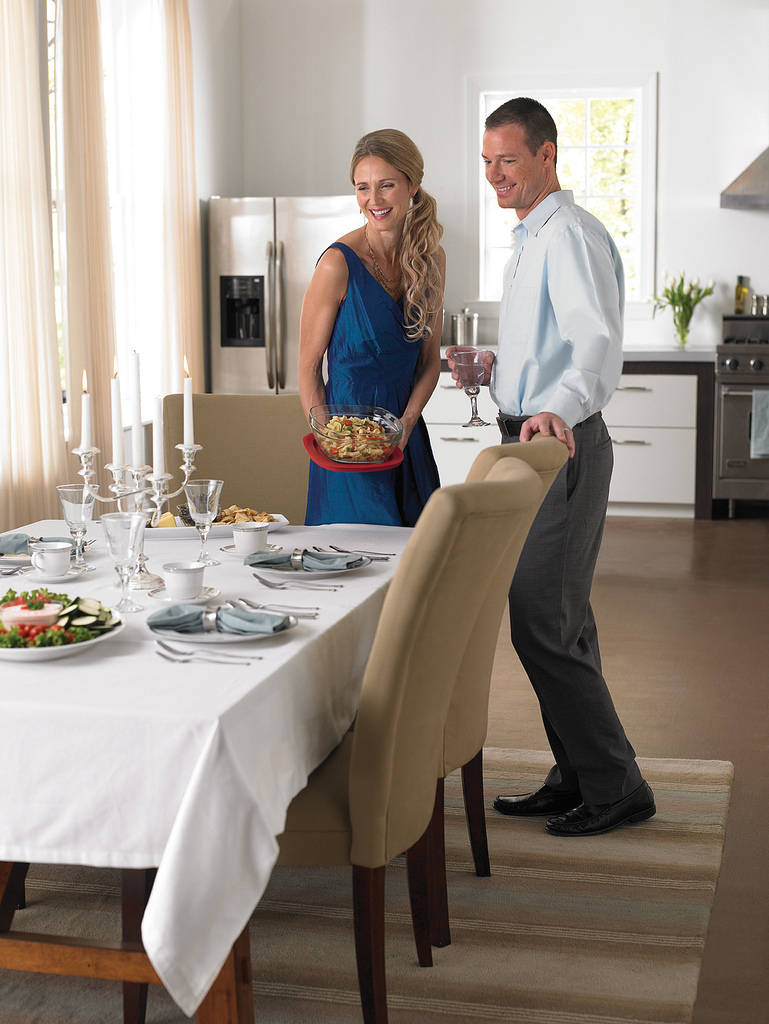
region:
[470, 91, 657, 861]
man wearing light blue shirt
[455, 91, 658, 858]
man wearing smoke gray pants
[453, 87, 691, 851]
man wearing black dress shoes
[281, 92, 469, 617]
woman wearing blue dress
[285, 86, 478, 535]
woman holding a dish of food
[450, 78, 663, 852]
man holding a wine glass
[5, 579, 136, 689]
plate with vegetables on it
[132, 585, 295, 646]
napkin with ring around it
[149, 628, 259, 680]
two forks on the table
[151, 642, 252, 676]
a utensil made for dining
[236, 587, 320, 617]
a utensil made for dining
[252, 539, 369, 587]
a plate made for dining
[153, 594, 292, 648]
a plate made for dining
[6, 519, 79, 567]
a plate made for dining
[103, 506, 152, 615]
a vessel made for drinking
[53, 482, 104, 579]
a vessel made for drinking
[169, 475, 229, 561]
a vessel made for drinking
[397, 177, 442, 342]
long ponytail hanging over the shoulder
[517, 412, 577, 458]
hand resting on top of the chair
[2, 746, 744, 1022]
area rug is laying on the floor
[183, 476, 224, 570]
clear, empty glass on the table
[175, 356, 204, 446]
candle is lit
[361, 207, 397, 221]
big smile on the face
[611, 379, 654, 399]
silver handle on the drawer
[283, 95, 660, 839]
a woman is standing next to a man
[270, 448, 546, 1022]
chair is pushed into the table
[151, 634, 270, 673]
silverware laying on the table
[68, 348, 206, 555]
a candelabra with white candles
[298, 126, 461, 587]
a woman with a blonde side ponytail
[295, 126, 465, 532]
woman wearing a blue dress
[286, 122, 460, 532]
woman holding dish of food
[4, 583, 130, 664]
a platter with vegetables and dip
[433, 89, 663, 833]
man holding glass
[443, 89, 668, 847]
man wearing light blue dress shirt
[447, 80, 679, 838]
man wearing gray dress pants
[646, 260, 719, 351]
vase of white flowers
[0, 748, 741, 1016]
a striped area rug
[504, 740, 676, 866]
the shoes are black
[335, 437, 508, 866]
the chair is tan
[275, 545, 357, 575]
napkin is on the plate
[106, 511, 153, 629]
the glass is empty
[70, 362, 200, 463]
the candles are lit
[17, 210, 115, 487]
the curtains are sheer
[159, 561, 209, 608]
the cup is on the dish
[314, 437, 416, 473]
the lid is red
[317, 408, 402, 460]
pasta is in the dish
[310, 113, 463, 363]
woman has blonde hair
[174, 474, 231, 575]
a glass on the table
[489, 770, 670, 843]
teh shoes are black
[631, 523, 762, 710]
the floor is color brown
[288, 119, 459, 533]
woman wears a blue dress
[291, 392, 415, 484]
a bowl with food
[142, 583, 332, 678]
utensils on side a dish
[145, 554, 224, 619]
a cup on a dish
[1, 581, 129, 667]
salad on a dish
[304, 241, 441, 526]
A blue sleeveless dress.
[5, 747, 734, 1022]
A white and tan area rug.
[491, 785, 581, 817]
A mans right black shoe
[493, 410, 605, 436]
Black belt with silver buckle.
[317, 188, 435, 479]
a person standing inside